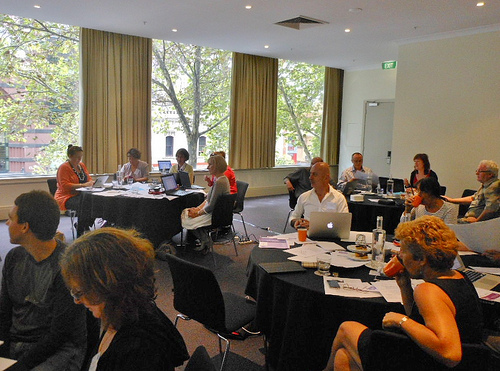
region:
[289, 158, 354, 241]
a man sits at a table with his laptop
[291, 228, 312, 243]
an orange cup sits on a pile of cluttered papers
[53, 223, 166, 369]
a lady with glasses looks down onto something in the foreground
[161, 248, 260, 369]
a black meeting chair sits on the floor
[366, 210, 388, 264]
a small bottle sits in the middle of the table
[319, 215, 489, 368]
a lady in the a lady in the foreground holds the cup up to drink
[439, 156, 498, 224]
a man in the background listens attentively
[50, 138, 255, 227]
aa group of people said at a table working on laptops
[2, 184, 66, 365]
a man sitting at the front looks to the right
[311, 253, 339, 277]
aa small clear cup sits on the edge of the table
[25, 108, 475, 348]
lots of people sitting around round tables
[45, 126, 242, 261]
people sitting around round table with black table cloths working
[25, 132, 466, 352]
several people sitting around tables as if at a seminar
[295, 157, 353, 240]
man sitting at table in front of Apple laptop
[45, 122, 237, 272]
lots of women sitting around table in front of laptops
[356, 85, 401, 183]
door to the room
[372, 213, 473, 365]
woman on right in black dress drinking out of cup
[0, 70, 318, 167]
trees lining the streets outside the window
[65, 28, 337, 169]
beige curtains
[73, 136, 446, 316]
lots of paperwork on the tables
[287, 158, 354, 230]
man in a white dress shirt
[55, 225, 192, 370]
woman with glasses looking at her table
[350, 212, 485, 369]
woman in a black dress drinking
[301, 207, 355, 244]
an apple laptop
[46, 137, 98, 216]
woman in an orange cardigan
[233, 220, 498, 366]
table with a black tablecloth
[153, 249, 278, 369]
black plastic chair with metal legs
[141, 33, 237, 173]
large window almost as tall as the wall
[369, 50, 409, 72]
an exit sign lit up green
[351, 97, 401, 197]
exit out of the room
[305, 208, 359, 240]
apple computer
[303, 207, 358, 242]
computer designed in California, assembled in China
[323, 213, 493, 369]
woman sitting with legs crossed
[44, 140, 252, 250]
table of women collaborating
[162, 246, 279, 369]
empty black and silver chair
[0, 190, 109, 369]
man wearing sweater looking to side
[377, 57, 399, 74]
green exit sign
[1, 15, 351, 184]
three windows with curtains drawn open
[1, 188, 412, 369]
carpeted floor of room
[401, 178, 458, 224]
person drinking from cup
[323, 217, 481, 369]
woman wearing black dress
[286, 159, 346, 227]
man wearing white shirt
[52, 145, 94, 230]
woman wearing orange cardigan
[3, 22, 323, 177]
three windows along the wall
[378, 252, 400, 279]
orange cup woman is drinking out of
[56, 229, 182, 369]
woman wearing black cardigan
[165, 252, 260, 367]
black chair no one is sitting in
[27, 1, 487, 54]
recessed lights in the ceiling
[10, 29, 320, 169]
tree outside the window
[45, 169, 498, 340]
three tables with black tablecloths